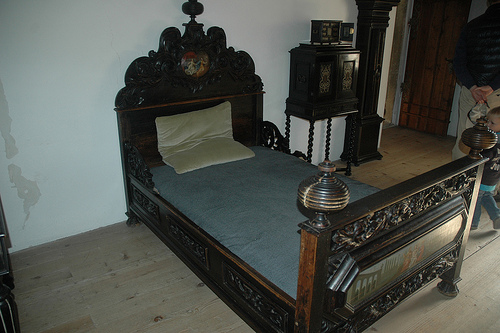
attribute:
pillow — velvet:
[168, 101, 255, 168]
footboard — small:
[272, 124, 494, 321]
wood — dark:
[262, 288, 279, 307]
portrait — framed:
[177, 47, 212, 81]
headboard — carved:
[112, 0, 265, 170]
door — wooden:
[363, 15, 472, 155]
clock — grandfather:
[178, 47, 215, 78]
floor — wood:
[14, 243, 209, 326]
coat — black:
[453, 9, 498, 89]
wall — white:
[2, 0, 356, 255]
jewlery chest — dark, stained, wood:
[286, 15, 363, 167]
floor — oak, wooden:
[0, 125, 500, 332]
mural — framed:
[326, 192, 467, 326]